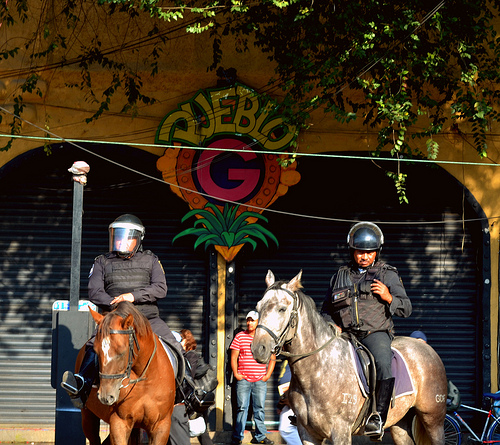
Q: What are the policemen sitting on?
A: Horses.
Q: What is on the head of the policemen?
A: Helmets.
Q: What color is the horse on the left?
A: Reddish brown.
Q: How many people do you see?
A: 5.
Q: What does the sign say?
A: Pueblo g.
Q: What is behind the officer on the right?
A: A bicycle.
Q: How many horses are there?
A: Two.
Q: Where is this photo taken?
A: Outside of a building.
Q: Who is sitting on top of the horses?
A: Policemen.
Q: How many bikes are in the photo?
A: One.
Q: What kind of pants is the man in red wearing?
A: Jeans.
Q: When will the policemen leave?
A: After they have finished securing the area.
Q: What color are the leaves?
A: Green.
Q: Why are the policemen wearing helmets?
A: For the protection of their heads.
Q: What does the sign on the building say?
A: PUEBLO.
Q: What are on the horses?
A: Police.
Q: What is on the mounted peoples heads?
A: Helmets.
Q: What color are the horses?
A: Brown.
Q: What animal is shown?
A: Horses.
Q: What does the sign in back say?
A: Pueblo G.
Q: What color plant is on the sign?
A: Green.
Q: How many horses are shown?
A: Two.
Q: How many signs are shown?
A: 1.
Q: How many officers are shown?
A: Two.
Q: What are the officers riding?
A: Horses.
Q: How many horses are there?
A: Two.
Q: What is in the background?
A: A building.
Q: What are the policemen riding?
A: Horses.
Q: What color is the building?
A: Yellow.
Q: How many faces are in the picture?
A: Five (including the horses).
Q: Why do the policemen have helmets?
A: To protect them from getting hurt.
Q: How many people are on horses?
A: Two.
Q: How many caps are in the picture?
A: Three.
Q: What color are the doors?
A: Black.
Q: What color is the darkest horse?
A: Red.